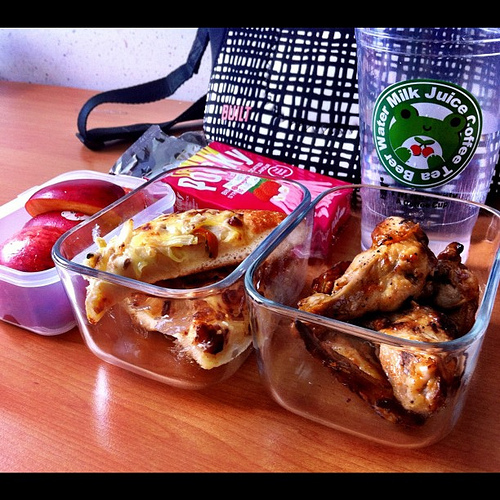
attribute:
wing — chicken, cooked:
[302, 217, 433, 309]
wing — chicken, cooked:
[370, 306, 450, 416]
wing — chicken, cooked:
[321, 338, 400, 422]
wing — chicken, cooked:
[421, 239, 483, 338]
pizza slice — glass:
[135, 277, 249, 367]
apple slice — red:
[23, 177, 122, 217]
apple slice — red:
[2, 226, 59, 269]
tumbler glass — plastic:
[358, 29, 486, 210]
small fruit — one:
[422, 135, 433, 159]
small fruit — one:
[408, 129, 419, 161]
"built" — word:
[213, 104, 255, 120]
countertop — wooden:
[7, 393, 249, 470]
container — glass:
[244, 185, 483, 446]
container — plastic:
[0, 167, 181, 337]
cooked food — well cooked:
[296, 216, 479, 423]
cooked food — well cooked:
[86, 205, 297, 375]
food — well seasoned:
[114, 204, 243, 300]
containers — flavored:
[78, 153, 453, 392]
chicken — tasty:
[316, 240, 455, 406]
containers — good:
[140, 148, 486, 425]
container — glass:
[282, 189, 491, 449]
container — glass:
[75, 171, 295, 371]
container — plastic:
[5, 171, 158, 330]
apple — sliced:
[24, 180, 155, 272]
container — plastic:
[13, 155, 170, 341]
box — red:
[149, 118, 379, 237]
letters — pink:
[205, 87, 291, 131]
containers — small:
[28, 164, 496, 403]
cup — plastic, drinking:
[335, 39, 485, 257]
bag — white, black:
[210, 36, 393, 215]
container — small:
[23, 156, 189, 355]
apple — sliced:
[21, 189, 141, 302]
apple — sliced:
[5, 180, 115, 264]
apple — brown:
[6, 178, 115, 278]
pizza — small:
[124, 197, 308, 352]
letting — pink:
[202, 82, 281, 133]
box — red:
[148, 126, 354, 226]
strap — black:
[72, 21, 212, 152]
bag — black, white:
[69, 30, 499, 202]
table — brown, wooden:
[2, 82, 497, 480]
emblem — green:
[370, 80, 479, 196]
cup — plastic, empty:
[356, 23, 496, 280]